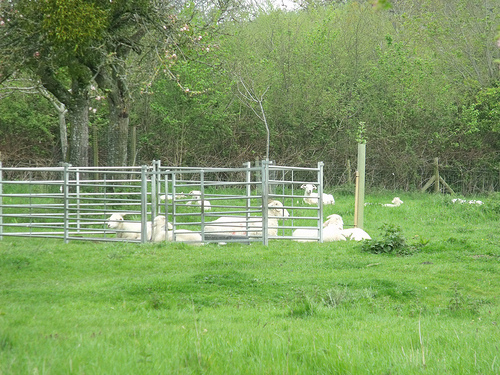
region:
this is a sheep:
[295, 211, 350, 249]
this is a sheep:
[295, 181, 340, 223]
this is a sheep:
[195, 193, 290, 267]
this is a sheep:
[142, 206, 187, 266]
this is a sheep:
[78, 183, 158, 275]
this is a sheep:
[375, 161, 409, 225]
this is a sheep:
[182, 175, 214, 223]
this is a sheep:
[135, 165, 200, 233]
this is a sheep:
[154, 171, 194, 213]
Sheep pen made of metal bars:
[0, 160, 322, 241]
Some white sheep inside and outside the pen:
[106, 180, 481, 241]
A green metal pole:
[355, 138, 365, 231]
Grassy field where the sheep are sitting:
[0, 186, 497, 373]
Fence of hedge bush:
[1, 153, 496, 195]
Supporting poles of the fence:
[420, 155, 455, 193]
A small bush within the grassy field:
[364, 221, 409, 254]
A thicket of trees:
[0, 0, 498, 188]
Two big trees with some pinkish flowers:
[0, 1, 207, 180]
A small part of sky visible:
[183, 0, 300, 17]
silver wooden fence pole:
[68, 168, 138, 175]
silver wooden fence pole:
[66, 180, 141, 190]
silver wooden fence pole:
[68, 195, 141, 205]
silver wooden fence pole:
[66, 216, 138, 223]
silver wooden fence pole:
[67, 233, 139, 243]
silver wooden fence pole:
[269, 162, 319, 171]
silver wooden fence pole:
[267, 175, 320, 187]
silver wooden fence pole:
[269, 192, 318, 200]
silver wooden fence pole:
[268, 213, 320, 221]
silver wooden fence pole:
[269, 223, 320, 231]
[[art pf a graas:
[263, 333, 289, 362]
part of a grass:
[270, 297, 302, 339]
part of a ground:
[309, 234, 339, 274]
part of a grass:
[296, 315, 326, 368]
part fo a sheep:
[320, 220, 334, 250]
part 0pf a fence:
[278, 178, 292, 200]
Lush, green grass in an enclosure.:
[1, 246, 499, 372]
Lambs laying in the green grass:
[106, 185, 371, 247]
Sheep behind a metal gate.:
[104, 205, 202, 243]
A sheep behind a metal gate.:
[202, 199, 290, 242]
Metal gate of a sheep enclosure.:
[1, 164, 95, 243]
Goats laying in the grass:
[291, 210, 374, 245]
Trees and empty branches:
[137, 1, 498, 142]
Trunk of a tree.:
[66, 111, 88, 165]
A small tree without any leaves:
[236, 72, 273, 157]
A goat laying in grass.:
[299, 179, 335, 206]